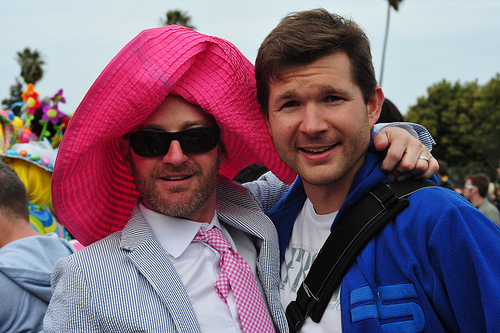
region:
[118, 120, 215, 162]
dark black sunglasses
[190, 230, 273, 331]
a man's pink and white tie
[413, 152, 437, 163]
a man's wedding band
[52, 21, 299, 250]
a large pink hat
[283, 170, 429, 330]
a black strap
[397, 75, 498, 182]
part of a large green tree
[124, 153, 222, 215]
a man's beard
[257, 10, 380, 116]
a man's short cut brown hair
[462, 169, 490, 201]
the head of a man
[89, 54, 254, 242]
a man wearing a pink hat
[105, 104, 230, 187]
a man wearing sunglasses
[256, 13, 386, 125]
a man with brown hair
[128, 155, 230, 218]
a man with facial hair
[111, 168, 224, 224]
a man with a beard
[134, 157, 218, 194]
a man with a mustache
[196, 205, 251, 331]
a man wearing a pink tie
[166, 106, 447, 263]
a man with his arm around another man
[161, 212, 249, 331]
a man wearing a white shirt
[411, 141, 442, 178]
a man wearing a ring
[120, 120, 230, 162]
black sunglasses on man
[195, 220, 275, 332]
pink tie on man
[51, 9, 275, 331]
man wearing pink hat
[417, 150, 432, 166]
silver ring on man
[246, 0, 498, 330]
man wearing blue jacket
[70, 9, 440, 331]
two men standing outside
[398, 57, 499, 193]
green trees in background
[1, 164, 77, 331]
man wearing gray hoodie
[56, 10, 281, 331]
man wearing striped jacket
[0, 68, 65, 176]
multi colored flowers in background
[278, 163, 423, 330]
black strap of man's bag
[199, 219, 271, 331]
pink and white checkered necktie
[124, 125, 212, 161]
black sunglasses of man in pink hat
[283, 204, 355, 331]
white shirt with gray lettering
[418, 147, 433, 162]
ring on man in pink hat's finger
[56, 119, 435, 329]
striped suit jacket of man in pink hat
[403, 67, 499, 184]
trees on the right side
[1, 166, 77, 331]
man wearing gray jacket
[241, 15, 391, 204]
head of a man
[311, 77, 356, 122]
eye of the man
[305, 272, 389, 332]
blue and white outfit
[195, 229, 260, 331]
pink and white tie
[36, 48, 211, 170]
hat on the man's head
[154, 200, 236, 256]
collar on the man's shirt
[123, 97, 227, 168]
sunglasses on the man's face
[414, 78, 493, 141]
tree in the background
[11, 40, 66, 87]
palm tree in the distance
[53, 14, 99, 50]
sky above the land